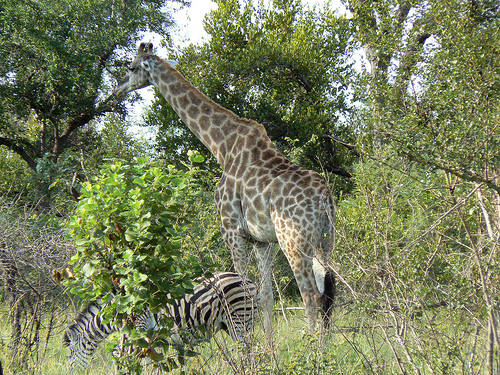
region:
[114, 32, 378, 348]
A giraffe is standing in the grass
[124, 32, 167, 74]
The giraffe has black horns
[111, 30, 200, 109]
The giraffe has its ears back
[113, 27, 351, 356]
The giraffe has brown spots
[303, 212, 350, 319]
The giraffe has a long black tail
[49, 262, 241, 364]
A zebra behind a bush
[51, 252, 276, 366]
The zebra is black and white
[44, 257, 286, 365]
The zebra has stripes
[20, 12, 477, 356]
Thick, green foliage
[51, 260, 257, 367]
The zebra is eating grass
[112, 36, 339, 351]
A brown and white giraffe.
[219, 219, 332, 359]
Four legs of a giraffe.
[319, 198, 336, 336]
Long thin tail of a giraffe.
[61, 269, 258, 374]
Two zebras grazing.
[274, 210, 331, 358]
The giraffes back left hind quarters.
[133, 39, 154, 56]
Two horns on a giraffes head.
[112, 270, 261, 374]
Black and white striped zebra grazing.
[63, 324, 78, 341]
Left ear of a zebra grazing.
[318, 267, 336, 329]
Furry black end of a giraffes tail.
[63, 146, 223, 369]
A small leafed tree in front of two zebras.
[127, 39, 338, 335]
giraffe standing near zebra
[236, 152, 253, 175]
brown spots on giraffe's back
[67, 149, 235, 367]
small tree in front of zebra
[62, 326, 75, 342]
zebra ear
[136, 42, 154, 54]
two horns on giraffe head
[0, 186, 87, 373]
dry gray bush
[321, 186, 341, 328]
long giraffe tail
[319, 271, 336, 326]
dark hair at end of giraffe tail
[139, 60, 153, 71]
giraffe ear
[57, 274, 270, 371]
zebra is eating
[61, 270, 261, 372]
the zebra next to the giraffe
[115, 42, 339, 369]
the tall giraffe looking to the left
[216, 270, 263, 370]
the backside of the zebra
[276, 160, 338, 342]
the back legs of the giraffe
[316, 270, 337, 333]
the end of the giraffes tail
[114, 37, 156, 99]
the giraffes head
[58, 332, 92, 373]
the zebras head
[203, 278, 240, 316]
the stripes on the zebra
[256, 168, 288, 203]
the pattern on the giraffe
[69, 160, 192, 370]
greenery in front of the zebra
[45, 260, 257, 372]
A zebra eating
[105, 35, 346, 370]
A giraffe with outstretched neck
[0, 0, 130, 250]
Tall trees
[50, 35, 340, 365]
A zebra and a giraffe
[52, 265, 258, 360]
Black and white striped zebra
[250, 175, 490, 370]
Bushes and grass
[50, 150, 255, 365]
A zebra behind a bush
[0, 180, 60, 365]
Branches from dead bushes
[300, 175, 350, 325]
Giraffe tail hanging down to the ground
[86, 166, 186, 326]
Green leaves growing on foliage